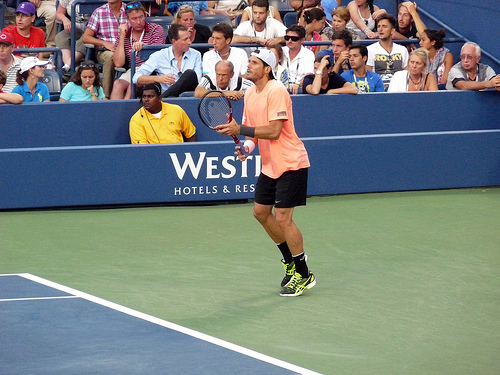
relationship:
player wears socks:
[199, 44, 319, 300] [277, 239, 315, 273]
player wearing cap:
[199, 44, 319, 300] [249, 43, 285, 78]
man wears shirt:
[360, 36, 410, 76] [362, 38, 410, 72]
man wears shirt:
[123, 78, 203, 143] [124, 101, 197, 147]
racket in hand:
[191, 81, 251, 160] [208, 111, 246, 136]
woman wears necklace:
[380, 44, 440, 97] [400, 70, 431, 89]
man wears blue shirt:
[4, 52, 30, 91] [11, 80, 51, 104]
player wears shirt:
[199, 44, 319, 300] [236, 80, 306, 182]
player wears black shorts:
[199, 44, 319, 300] [245, 157, 317, 218]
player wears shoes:
[199, 44, 319, 300] [280, 265, 320, 299]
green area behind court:
[200, 210, 500, 349] [4, 205, 467, 375]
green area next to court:
[200, 210, 500, 349] [4, 205, 467, 375]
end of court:
[31, 269, 262, 348] [4, 205, 467, 375]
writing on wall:
[165, 144, 260, 205] [0, 123, 493, 215]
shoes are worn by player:
[280, 265, 320, 299] [199, 44, 319, 300]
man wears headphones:
[123, 78, 203, 143] [142, 79, 165, 93]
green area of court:
[200, 210, 500, 349] [4, 205, 467, 375]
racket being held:
[191, 81, 251, 160] [201, 114, 247, 170]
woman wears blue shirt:
[56, 59, 110, 107] [55, 80, 103, 102]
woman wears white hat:
[10, 52, 61, 106] [16, 54, 56, 73]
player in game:
[199, 44, 319, 300] [27, 45, 471, 313]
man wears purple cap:
[0, 1, 50, 44] [13, 3, 40, 20]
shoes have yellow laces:
[280, 265, 320, 299] [282, 267, 308, 288]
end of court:
[19, 271, 320, 375] [4, 205, 467, 375]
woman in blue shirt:
[10, 52, 61, 106] [7, 77, 52, 104]